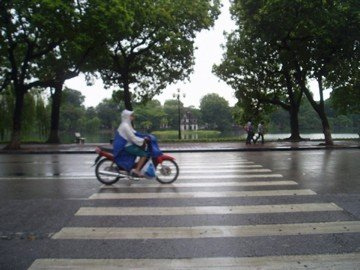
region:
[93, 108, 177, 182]
A person riding a motorcycle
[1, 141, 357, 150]
The people are on the side walk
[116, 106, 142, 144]
Person on motorcycle with a white hoodie on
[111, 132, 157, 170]
Person one motorcycle has something blue covering them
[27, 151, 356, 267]
There are white lines on the street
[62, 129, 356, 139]
Alake beside the road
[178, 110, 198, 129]
A white house on the other side of lake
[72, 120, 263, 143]
People standing and walking on the side of the road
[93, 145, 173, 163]
The motorcycle is red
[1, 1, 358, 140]
There are many trees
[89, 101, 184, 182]
person riding motorcycle down road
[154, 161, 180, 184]
black wheel of motorcycle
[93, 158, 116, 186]
black wheel of motorcycle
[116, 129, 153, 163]
blue tarp on person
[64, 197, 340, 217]
white stripe on street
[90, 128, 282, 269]
white stripes on street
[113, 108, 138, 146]
white jacket on person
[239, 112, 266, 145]
two people walking down street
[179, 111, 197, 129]
small white building in background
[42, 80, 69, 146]
brown tree trunk on grass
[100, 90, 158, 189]
this is a person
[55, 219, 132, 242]
a line on the road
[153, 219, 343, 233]
a line on the road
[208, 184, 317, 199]
a line on the road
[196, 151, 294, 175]
a line on the road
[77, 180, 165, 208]
a line on the road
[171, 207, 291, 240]
a line on the road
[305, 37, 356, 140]
this is a tree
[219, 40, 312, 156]
this is a tree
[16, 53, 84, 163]
this is a tree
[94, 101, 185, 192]
person riding motor skooter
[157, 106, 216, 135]
house beyond trees in back of photo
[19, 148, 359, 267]
white cross walk lines on street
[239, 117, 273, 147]
people walking on sidewalk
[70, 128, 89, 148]
bench next to sidewalk and pond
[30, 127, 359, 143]
pond in front of house and next to sidewalk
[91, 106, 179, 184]
person riding red motor skooter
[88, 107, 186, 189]
person with white jacket and blue tarp on motor skooter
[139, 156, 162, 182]
white and blue bag hanging from motor skooter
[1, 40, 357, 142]
trees outlining sidewalk and pond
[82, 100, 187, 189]
person riding bicycle in street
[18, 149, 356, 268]
white lines in street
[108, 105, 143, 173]
rain parka on person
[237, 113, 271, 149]
people walking on sidewalk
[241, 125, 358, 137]
body of water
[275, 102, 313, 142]
tree trunk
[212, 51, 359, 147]
tall trees on sidewalk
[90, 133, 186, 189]
red motorcycle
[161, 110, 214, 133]
house in field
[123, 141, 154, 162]
pair of green pants